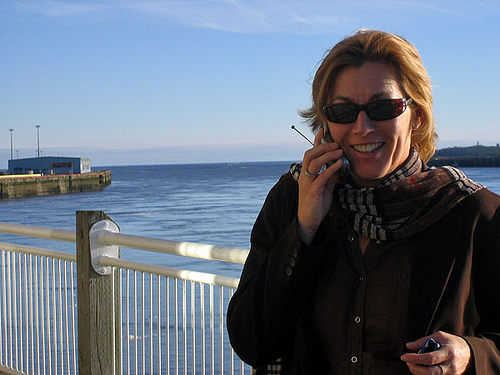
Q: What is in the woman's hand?
A: Cell phone.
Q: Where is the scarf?
A: Around the woman's neck.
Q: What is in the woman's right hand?
A: Cell phone.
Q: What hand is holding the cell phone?
A: Right.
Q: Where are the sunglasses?
A: On the brunette's face.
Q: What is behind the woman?
A: A fence.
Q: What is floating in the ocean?
A: A barge.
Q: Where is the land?
A: Behind the woman.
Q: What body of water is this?
A: An ocean.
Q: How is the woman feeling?
A: Happy.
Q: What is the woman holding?
A: A cell phone.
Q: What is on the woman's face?
A: Sunglasses.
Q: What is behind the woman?
A: A body of blue water.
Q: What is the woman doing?
A: Talking on the phone.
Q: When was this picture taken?
A: Afternoon.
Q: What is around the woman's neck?
A: A scarf.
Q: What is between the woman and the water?
A: A railing.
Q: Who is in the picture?
A: A woman.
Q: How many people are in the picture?
A: One.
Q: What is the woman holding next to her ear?
A: Phone.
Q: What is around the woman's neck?
A: Scarf.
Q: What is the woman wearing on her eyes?
A: Glasses.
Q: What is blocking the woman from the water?
A: Fence.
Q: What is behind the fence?
A: Water.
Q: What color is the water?
A: Blue.